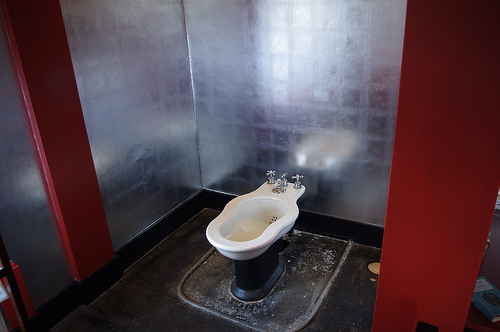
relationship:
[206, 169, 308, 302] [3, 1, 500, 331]
toilet in bathroom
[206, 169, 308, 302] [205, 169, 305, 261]
toilet has upper piece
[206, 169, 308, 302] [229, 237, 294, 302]
toilet has base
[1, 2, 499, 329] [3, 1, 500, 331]
walls in bathroom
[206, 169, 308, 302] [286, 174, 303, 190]
toilet has faucets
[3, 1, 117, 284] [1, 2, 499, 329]
plank on walls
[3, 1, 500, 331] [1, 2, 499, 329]
bathroom has walls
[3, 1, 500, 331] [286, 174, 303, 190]
bathroom has faucets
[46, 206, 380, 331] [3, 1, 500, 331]
floor in bathroom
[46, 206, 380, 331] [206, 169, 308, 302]
floor underneath toilet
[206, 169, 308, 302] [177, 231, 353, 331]
toilet has bottom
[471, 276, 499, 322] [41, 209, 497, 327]
book on ground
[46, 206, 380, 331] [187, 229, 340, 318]
floor has specks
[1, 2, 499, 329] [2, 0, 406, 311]
walls have paper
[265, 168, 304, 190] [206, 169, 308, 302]
faucets on toilet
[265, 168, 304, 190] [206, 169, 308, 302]
faucets on back of toilet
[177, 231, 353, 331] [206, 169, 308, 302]
bottom around toilet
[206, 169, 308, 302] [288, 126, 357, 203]
toilet has reflection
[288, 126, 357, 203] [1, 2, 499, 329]
reflection in walls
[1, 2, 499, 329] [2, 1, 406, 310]
walls has patterns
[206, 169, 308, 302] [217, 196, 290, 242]
toilet has interior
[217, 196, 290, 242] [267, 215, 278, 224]
interior has holes